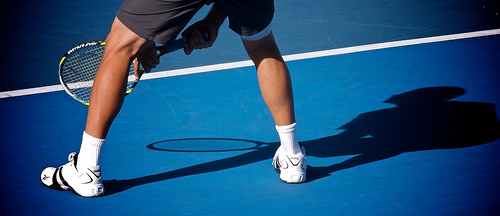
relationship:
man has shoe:
[113, 2, 287, 128] [44, 160, 112, 208]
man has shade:
[113, 2, 287, 128] [100, 87, 499, 196]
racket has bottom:
[63, 32, 132, 106] [166, 37, 202, 61]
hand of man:
[179, 22, 216, 53] [113, 2, 287, 128]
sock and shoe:
[74, 130, 106, 168] [41, 151, 112, 199]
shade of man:
[100, 87, 499, 196] [37, 2, 317, 199]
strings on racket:
[72, 52, 105, 82] [63, 32, 132, 106]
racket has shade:
[63, 32, 132, 106] [100, 87, 499, 196]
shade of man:
[147, 127, 200, 148] [37, 2, 317, 199]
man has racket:
[37, 2, 317, 199] [63, 32, 132, 106]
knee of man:
[101, 23, 134, 51] [37, 2, 317, 199]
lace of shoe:
[63, 148, 80, 164] [44, 160, 112, 208]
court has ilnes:
[297, 22, 449, 149] [307, 38, 375, 75]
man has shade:
[37, 2, 317, 199] [100, 87, 499, 196]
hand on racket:
[179, 20, 220, 55] [63, 32, 132, 106]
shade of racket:
[100, 87, 499, 196] [63, 32, 132, 106]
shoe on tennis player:
[41, 151, 112, 199] [28, 2, 315, 202]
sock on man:
[74, 137, 121, 169] [37, 2, 317, 199]